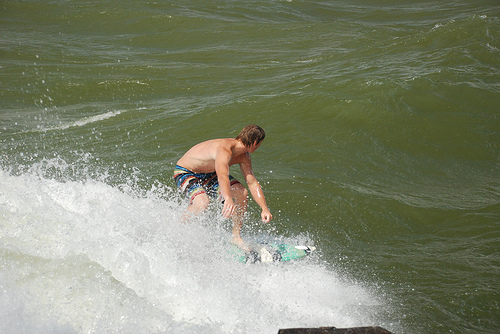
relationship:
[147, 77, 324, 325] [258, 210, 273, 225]
man has hand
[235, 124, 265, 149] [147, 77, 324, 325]
hair on man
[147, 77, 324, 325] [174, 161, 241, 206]
man wearing shorts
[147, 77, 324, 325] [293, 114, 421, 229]
man surfing on water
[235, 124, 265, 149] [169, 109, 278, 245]
hair of surfing man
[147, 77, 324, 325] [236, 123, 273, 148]
man surfing with hair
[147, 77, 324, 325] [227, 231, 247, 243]
man left foot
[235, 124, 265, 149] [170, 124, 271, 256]
hair of surfer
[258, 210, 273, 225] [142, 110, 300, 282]
hand of man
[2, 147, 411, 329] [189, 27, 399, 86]
wave of ocean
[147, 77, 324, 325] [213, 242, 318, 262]
man on surfboard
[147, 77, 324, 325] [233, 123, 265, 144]
man has hair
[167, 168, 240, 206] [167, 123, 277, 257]
shorts on man